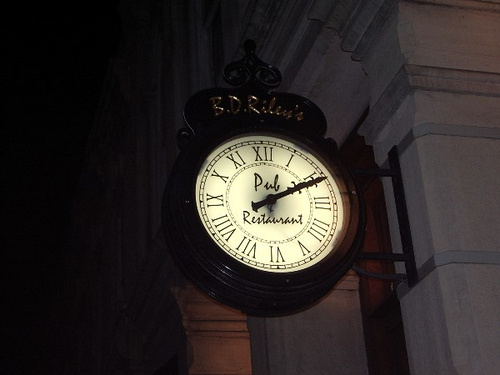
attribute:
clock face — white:
[192, 128, 347, 278]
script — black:
[241, 168, 306, 226]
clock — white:
[158, 82, 369, 319]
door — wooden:
[332, 132, 407, 373]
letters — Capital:
[314, 191, 332, 211]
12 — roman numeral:
[249, 138, 278, 168]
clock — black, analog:
[178, 126, 355, 286]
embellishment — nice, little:
[222, 38, 286, 93]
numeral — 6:
[265, 241, 287, 270]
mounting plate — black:
[336, 122, 422, 308]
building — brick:
[169, 0, 499, 374]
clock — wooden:
[145, 43, 359, 319]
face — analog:
[162, 110, 366, 285]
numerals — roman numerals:
[267, 235, 289, 269]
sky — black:
[1, 3, 124, 370]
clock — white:
[191, 135, 351, 276]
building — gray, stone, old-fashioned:
[31, 2, 499, 367]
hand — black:
[249, 172, 327, 211]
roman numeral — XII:
[251, 141, 275, 163]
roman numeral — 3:
[312, 191, 334, 212]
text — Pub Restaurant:
[238, 171, 307, 226]